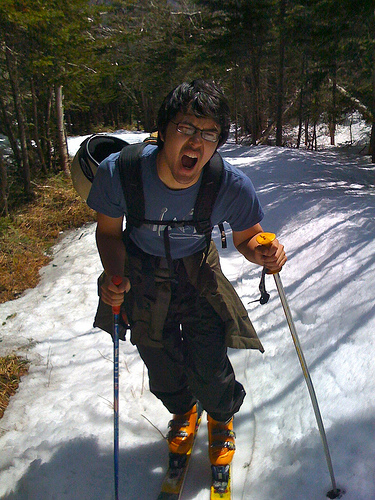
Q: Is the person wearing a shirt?
A: Yes, the person is wearing a shirt.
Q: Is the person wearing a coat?
A: No, the person is wearing a shirt.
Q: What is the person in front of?
A: The person is in front of the tree.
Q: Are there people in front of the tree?
A: Yes, there is a person in front of the tree.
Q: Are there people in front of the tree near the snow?
A: Yes, there is a person in front of the tree.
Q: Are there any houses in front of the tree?
A: No, there is a person in front of the tree.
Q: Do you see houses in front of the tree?
A: No, there is a person in front of the tree.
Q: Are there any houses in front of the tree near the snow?
A: No, there is a person in front of the tree.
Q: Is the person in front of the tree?
A: Yes, the person is in front of the tree.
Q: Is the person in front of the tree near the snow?
A: Yes, the person is in front of the tree.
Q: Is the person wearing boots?
A: Yes, the person is wearing boots.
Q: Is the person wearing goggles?
A: No, the person is wearing boots.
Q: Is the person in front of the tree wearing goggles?
A: No, the person is wearing boots.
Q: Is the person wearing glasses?
A: Yes, the person is wearing glasses.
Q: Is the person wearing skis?
A: No, the person is wearing glasses.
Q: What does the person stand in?
A: The person stands in the snow.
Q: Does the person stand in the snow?
A: Yes, the person stands in the snow.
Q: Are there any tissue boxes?
A: No, there are no tissue boxes.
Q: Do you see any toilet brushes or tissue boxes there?
A: No, there are no tissue boxes or toilet brushes.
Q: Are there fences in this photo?
A: No, there are no fences.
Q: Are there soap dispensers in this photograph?
A: No, there are no soap dispensers.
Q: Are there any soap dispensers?
A: No, there are no soap dispensers.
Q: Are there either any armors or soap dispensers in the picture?
A: No, there are no soap dispensers or armors.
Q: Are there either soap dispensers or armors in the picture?
A: No, there are no soap dispensers or armors.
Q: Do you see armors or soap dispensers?
A: No, there are no soap dispensers or armors.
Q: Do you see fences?
A: No, there are no fences.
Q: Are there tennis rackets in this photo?
A: No, there are no tennis rackets.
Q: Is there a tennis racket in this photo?
A: No, there are no rackets.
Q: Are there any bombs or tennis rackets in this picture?
A: No, there are no tennis rackets or bombs.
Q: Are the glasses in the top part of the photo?
A: Yes, the glasses are in the top of the image.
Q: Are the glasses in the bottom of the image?
A: No, the glasses are in the top of the image.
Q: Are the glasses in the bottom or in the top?
A: The glasses are in the top of the image.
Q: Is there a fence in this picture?
A: No, there are no fences.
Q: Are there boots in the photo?
A: Yes, there are boots.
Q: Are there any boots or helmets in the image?
A: Yes, there are boots.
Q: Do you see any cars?
A: No, there are no cars.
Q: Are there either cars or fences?
A: No, there are no cars or fences.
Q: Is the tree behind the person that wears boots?
A: Yes, the tree is behind the person.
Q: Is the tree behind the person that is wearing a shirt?
A: Yes, the tree is behind the person.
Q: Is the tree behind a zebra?
A: No, the tree is behind the person.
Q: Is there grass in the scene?
A: Yes, there is grass.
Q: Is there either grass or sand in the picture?
A: Yes, there is grass.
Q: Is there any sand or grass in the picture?
A: Yes, there is grass.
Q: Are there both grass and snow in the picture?
A: Yes, there are both grass and snow.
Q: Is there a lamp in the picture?
A: No, there are no lamps.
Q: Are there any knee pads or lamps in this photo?
A: No, there are no lamps or knee pads.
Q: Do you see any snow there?
A: Yes, there is snow.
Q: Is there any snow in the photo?
A: Yes, there is snow.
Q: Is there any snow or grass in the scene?
A: Yes, there is snow.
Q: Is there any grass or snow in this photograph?
A: Yes, there is snow.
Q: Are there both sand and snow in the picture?
A: No, there is snow but no sand.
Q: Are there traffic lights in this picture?
A: No, there are no traffic lights.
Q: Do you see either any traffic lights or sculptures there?
A: No, there are no traffic lights or sculptures.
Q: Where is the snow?
A: The snow is on the ground.